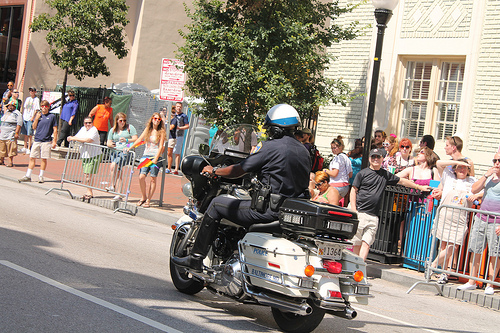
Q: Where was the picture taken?
A: It was taken at the sidewalk.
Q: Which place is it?
A: It is a sidewalk.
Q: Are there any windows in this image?
A: Yes, there are windows.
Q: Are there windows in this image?
A: Yes, there are windows.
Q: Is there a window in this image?
A: Yes, there are windows.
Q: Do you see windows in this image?
A: Yes, there are windows.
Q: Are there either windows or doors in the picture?
A: Yes, there are windows.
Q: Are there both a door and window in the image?
A: No, there are windows but no doors.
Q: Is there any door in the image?
A: No, there are no doors.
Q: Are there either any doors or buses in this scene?
A: No, there are no doors or buses.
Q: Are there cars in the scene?
A: No, there are no cars.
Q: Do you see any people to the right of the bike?
A: Yes, there is a person to the right of the bike.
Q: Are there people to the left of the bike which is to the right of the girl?
A: No, the person is to the right of the bike.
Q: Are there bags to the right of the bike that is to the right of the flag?
A: No, there is a person to the right of the bike.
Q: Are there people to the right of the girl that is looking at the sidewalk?
A: Yes, there is a person to the right of the girl.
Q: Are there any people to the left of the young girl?
A: No, the person is to the right of the girl.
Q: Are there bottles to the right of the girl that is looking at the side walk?
A: No, there is a person to the right of the girl.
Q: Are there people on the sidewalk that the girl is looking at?
A: Yes, there is a person on the sidewalk.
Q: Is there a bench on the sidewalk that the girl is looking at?
A: No, there is a person on the side walk.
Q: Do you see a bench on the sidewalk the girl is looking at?
A: No, there is a person on the side walk.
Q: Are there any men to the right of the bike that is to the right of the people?
A: Yes, there is a man to the right of the bike.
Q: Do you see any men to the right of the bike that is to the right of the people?
A: Yes, there is a man to the right of the bike.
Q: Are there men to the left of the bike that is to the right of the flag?
A: No, the man is to the right of the bike.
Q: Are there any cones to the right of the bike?
A: No, there is a man to the right of the bike.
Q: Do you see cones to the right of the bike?
A: No, there is a man to the right of the bike.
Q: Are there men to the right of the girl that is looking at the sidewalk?
A: Yes, there is a man to the right of the girl.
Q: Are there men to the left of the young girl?
A: No, the man is to the right of the girl.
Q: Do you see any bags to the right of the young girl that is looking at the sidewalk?
A: No, there is a man to the right of the girl.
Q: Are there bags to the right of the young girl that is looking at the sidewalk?
A: No, there is a man to the right of the girl.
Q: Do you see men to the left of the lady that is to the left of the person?
A: Yes, there is a man to the left of the lady.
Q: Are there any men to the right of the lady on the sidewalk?
A: No, the man is to the left of the lady.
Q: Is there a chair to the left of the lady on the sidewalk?
A: No, there is a man to the left of the lady.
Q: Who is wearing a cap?
A: The man is wearing a cap.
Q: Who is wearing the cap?
A: The man is wearing a cap.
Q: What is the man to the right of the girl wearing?
A: The man is wearing a cap.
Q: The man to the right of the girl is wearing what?
A: The man is wearing a cap.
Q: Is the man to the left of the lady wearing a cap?
A: Yes, the man is wearing a cap.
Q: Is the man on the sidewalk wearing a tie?
A: No, the man is wearing a cap.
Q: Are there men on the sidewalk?
A: Yes, there is a man on the sidewalk.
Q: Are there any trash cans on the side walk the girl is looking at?
A: No, there is a man on the sidewalk.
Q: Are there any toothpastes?
A: No, there are no toothpastes.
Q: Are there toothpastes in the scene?
A: No, there are no toothpastes.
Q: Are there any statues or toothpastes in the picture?
A: No, there are no toothpastes or statues.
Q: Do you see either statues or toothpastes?
A: No, there are no toothpastes or statues.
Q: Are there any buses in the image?
A: No, there are no buses.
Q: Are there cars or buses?
A: No, there are no buses or cars.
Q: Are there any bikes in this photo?
A: Yes, there is a bike.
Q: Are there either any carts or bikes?
A: Yes, there is a bike.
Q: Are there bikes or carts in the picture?
A: Yes, there is a bike.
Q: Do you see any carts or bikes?
A: Yes, there is a bike.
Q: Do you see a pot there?
A: No, there are no pots.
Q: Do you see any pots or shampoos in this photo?
A: No, there are no pots or shampoos.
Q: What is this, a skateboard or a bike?
A: This is a bike.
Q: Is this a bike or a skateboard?
A: This is a bike.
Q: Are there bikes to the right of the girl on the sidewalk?
A: Yes, there is a bike to the right of the girl.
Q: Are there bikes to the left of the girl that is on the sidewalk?
A: No, the bike is to the right of the girl.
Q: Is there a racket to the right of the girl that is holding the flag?
A: No, there is a bike to the right of the girl.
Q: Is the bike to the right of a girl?
A: Yes, the bike is to the right of a girl.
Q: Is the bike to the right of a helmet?
A: No, the bike is to the right of a girl.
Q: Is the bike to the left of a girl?
A: No, the bike is to the right of a girl.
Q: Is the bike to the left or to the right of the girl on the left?
A: The bike is to the right of the girl.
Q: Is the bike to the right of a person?
A: No, the bike is to the left of a person.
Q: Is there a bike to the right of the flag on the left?
A: Yes, there is a bike to the right of the flag.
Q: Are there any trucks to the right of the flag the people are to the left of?
A: No, there is a bike to the right of the flag.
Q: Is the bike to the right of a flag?
A: Yes, the bike is to the right of a flag.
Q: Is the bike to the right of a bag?
A: No, the bike is to the right of a flag.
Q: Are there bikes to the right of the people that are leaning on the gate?
A: Yes, there is a bike to the right of the people.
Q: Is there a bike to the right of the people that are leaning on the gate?
A: Yes, there is a bike to the right of the people.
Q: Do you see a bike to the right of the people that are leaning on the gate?
A: Yes, there is a bike to the right of the people.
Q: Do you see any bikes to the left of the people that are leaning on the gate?
A: No, the bike is to the right of the people.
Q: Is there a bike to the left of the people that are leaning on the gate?
A: No, the bike is to the right of the people.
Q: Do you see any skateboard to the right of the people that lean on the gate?
A: No, there is a bike to the right of the people.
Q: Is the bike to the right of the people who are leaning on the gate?
A: Yes, the bike is to the right of the people.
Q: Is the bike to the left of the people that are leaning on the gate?
A: No, the bike is to the right of the people.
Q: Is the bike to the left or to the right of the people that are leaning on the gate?
A: The bike is to the right of the people.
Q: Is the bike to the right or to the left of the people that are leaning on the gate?
A: The bike is to the right of the people.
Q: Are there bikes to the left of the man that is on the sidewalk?
A: Yes, there is a bike to the left of the man.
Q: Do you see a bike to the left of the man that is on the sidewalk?
A: Yes, there is a bike to the left of the man.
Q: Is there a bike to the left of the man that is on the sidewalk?
A: Yes, there is a bike to the left of the man.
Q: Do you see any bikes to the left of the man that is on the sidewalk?
A: Yes, there is a bike to the left of the man.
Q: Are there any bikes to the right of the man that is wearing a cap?
A: No, the bike is to the left of the man.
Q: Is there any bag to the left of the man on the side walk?
A: No, there is a bike to the left of the man.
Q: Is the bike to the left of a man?
A: Yes, the bike is to the left of a man.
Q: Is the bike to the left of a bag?
A: No, the bike is to the left of a man.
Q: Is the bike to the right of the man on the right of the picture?
A: No, the bike is to the left of the man.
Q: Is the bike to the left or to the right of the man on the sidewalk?
A: The bike is to the left of the man.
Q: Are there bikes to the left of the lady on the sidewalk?
A: Yes, there is a bike to the left of the lady.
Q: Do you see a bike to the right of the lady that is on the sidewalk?
A: No, the bike is to the left of the lady.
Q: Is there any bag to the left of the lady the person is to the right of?
A: No, there is a bike to the left of the lady.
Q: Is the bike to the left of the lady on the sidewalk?
A: Yes, the bike is to the left of the lady.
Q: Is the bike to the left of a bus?
A: No, the bike is to the left of the lady.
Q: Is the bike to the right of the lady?
A: No, the bike is to the left of the lady.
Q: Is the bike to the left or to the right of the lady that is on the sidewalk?
A: The bike is to the left of the lady.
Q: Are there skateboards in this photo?
A: No, there are no skateboards.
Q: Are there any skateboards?
A: No, there are no skateboards.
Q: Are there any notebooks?
A: No, there are no notebooks.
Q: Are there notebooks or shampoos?
A: No, there are no notebooks or shampoos.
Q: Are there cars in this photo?
A: No, there are no cars.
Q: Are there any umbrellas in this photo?
A: No, there are no umbrellas.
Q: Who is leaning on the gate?
A: The people are leaning on the gate.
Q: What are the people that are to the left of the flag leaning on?
A: The people are leaning on the gate.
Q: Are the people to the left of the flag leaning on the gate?
A: Yes, the people are leaning on the gate.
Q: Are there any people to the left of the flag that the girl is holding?
A: Yes, there are people to the left of the flag.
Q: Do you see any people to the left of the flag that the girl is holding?
A: Yes, there are people to the left of the flag.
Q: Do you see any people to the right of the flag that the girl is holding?
A: No, the people are to the left of the flag.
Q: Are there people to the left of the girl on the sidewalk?
A: Yes, there are people to the left of the girl.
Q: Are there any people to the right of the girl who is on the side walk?
A: No, the people are to the left of the girl.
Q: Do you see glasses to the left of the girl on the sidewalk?
A: No, there are people to the left of the girl.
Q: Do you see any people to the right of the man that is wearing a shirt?
A: Yes, there are people to the right of the man.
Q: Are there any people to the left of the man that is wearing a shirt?
A: No, the people are to the right of the man.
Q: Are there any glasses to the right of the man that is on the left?
A: No, there are people to the right of the man.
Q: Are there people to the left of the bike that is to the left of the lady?
A: Yes, there are people to the left of the bike.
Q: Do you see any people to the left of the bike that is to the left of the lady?
A: Yes, there are people to the left of the bike.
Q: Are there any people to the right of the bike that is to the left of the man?
A: No, the people are to the left of the bike.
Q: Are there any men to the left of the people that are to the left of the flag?
A: Yes, there is a man to the left of the people.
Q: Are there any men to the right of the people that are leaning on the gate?
A: No, the man is to the left of the people.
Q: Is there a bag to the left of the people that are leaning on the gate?
A: No, there is a man to the left of the people.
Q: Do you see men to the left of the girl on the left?
A: Yes, there is a man to the left of the girl.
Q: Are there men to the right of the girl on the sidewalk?
A: No, the man is to the left of the girl.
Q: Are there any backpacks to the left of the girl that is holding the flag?
A: No, there is a man to the left of the girl.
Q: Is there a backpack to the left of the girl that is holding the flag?
A: No, there is a man to the left of the girl.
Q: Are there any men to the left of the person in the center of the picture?
A: Yes, there is a man to the left of the person.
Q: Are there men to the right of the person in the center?
A: No, the man is to the left of the person.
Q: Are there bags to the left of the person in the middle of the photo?
A: No, there is a man to the left of the person.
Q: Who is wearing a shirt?
A: The man is wearing a shirt.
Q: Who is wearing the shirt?
A: The man is wearing a shirt.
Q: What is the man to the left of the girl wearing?
A: The man is wearing a shirt.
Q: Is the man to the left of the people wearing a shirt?
A: Yes, the man is wearing a shirt.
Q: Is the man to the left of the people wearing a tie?
A: No, the man is wearing a shirt.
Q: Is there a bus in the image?
A: No, there are no buses.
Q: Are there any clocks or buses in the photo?
A: No, there are no buses or clocks.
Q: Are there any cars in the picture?
A: No, there are no cars.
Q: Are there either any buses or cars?
A: No, there are no cars or buses.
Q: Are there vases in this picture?
A: No, there are no vases.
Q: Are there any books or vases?
A: No, there are no vases or books.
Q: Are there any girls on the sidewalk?
A: Yes, there is a girl on the sidewalk.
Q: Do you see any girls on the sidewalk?
A: Yes, there is a girl on the sidewalk.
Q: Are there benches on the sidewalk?
A: No, there is a girl on the sidewalk.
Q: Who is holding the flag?
A: The girl is holding the flag.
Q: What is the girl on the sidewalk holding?
A: The girl is holding the flag.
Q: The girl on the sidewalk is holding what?
A: The girl is holding the flag.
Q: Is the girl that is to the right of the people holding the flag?
A: Yes, the girl is holding the flag.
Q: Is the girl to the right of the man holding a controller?
A: No, the girl is holding the flag.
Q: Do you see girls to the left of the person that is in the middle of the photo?
A: Yes, there is a girl to the left of the person.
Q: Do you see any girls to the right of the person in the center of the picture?
A: No, the girl is to the left of the person.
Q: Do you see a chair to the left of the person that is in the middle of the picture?
A: No, there is a girl to the left of the person.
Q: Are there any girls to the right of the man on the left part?
A: Yes, there is a girl to the right of the man.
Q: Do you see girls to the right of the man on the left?
A: Yes, there is a girl to the right of the man.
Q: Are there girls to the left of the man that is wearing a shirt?
A: No, the girl is to the right of the man.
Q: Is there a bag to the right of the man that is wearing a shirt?
A: No, there is a girl to the right of the man.